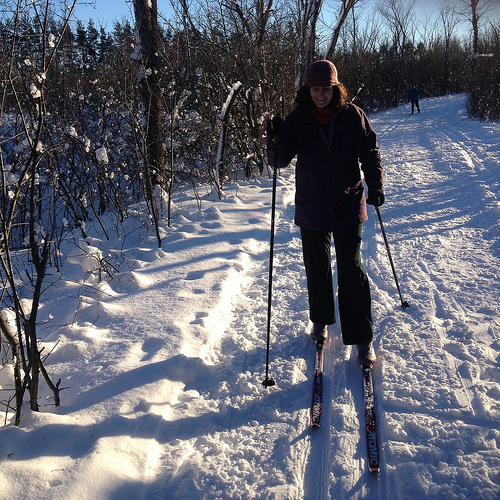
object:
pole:
[262, 157, 278, 386]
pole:
[365, 195, 407, 311]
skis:
[310, 339, 382, 473]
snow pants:
[300, 226, 374, 346]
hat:
[303, 60, 338, 84]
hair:
[295, 83, 348, 108]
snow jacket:
[269, 103, 384, 225]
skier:
[408, 85, 422, 114]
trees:
[0, 0, 500, 428]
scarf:
[308, 107, 334, 153]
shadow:
[0, 92, 500, 500]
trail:
[264, 58, 384, 364]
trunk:
[130, 44, 172, 186]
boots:
[311, 323, 328, 339]